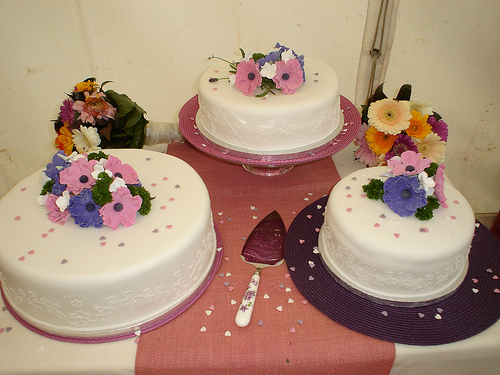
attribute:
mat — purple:
[280, 176, 498, 339]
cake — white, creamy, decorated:
[323, 153, 474, 303]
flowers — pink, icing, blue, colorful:
[358, 149, 445, 218]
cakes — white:
[4, 49, 500, 344]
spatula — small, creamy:
[227, 210, 290, 328]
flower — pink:
[388, 154, 428, 178]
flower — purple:
[386, 177, 424, 212]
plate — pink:
[178, 80, 362, 164]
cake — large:
[3, 148, 220, 341]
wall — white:
[4, 9, 374, 121]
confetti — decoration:
[199, 198, 314, 336]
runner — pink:
[135, 142, 398, 369]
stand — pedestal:
[238, 157, 300, 174]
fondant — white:
[325, 199, 476, 298]